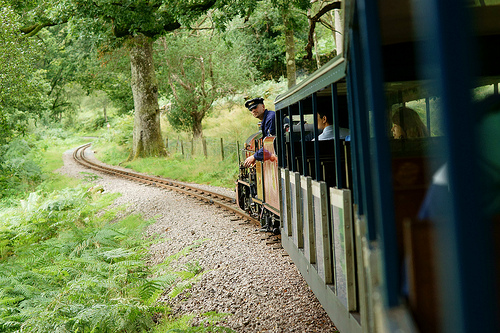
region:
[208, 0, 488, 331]
this is a train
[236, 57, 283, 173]
this is a man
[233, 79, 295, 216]
man standing on the train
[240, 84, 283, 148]
this is the conductor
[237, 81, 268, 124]
the man is wearing a hat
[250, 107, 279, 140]
the man is wearing a blue shirt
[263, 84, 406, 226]
open side on train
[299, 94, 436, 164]
people sitting on the train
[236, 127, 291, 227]
yellow front on train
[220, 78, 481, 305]
blue and silver tourist train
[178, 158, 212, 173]
short green and brown grass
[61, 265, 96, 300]
short green and brown grass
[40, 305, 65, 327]
short green and brown grass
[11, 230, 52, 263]
short green and brown grass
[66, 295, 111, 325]
short green and brown grass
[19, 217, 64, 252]
short green and brown grass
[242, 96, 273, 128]
The driver of the train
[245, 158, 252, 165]
The hand hanging out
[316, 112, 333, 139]
Person sitting on the train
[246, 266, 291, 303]
Gravel along the tracks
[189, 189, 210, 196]
The train tracks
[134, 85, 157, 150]
A tree trunk next to the tracks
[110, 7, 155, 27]
Green leaves on a tree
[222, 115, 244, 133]
Grass on the ground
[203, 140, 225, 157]
Poles supporting the fence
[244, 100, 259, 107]
Hat on the head of driver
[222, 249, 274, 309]
pile of gravel beside tracks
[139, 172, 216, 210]
brown metal train tracks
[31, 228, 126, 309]
bushes with green leaves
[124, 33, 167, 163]
large brown tree trunk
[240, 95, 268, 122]
man in black hat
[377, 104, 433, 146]
woman with long brown hair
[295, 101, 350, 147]
man with short black hair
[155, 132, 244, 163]
row of brown wooden fence post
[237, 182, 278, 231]
black metal train wheels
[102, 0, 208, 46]
trees with green leaves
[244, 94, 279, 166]
Train conductor operating train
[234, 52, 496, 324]
Operating the long train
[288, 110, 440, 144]
Passengers on the train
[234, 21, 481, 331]
Engine pulling train cars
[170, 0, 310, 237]
Train going through wooded area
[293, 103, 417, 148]
Passengers looking at scenery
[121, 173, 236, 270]
Gravel beside the tracks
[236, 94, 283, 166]
Conductor wearing a hat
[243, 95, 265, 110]
The black conductor hat.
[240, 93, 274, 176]
The conductor looking behind the train.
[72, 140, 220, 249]
The rusted train tracks.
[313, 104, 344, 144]
Man sitting on the train.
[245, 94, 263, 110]
hat worn by human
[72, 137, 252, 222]
tracks in front of train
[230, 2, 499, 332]
train behind tracks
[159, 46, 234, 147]
tree in front of train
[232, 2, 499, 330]
train approaching tree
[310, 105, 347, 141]
human rides train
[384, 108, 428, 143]
human wears hair long